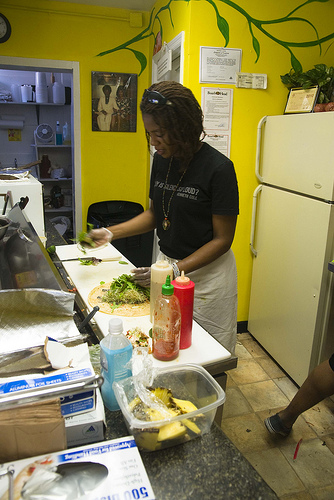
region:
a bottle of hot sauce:
[151, 273, 181, 361]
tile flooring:
[258, 448, 332, 495]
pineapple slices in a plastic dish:
[124, 348, 227, 449]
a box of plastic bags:
[2, 427, 148, 497]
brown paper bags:
[4, 395, 66, 458]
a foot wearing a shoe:
[261, 408, 300, 441]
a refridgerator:
[247, 109, 332, 383]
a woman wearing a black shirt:
[139, 139, 242, 262]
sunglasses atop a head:
[139, 84, 180, 109]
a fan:
[32, 121, 56, 145]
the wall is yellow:
[85, 135, 150, 194]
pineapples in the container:
[113, 376, 229, 457]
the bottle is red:
[172, 265, 201, 371]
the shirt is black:
[129, 143, 238, 270]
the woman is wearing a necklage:
[118, 85, 190, 235]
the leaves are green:
[72, 258, 157, 319]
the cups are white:
[31, 70, 57, 113]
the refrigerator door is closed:
[248, 133, 320, 362]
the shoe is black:
[249, 398, 316, 458]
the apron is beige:
[149, 227, 248, 364]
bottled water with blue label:
[98, 314, 135, 414]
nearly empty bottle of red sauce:
[148, 266, 184, 363]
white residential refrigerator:
[245, 97, 332, 395]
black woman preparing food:
[71, 68, 234, 313]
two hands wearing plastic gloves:
[74, 216, 185, 313]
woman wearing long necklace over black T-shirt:
[133, 76, 209, 262]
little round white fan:
[30, 117, 57, 149]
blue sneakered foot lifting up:
[260, 391, 299, 444]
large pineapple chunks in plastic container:
[111, 360, 224, 441]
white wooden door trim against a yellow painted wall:
[72, 58, 91, 204]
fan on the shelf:
[35, 123, 62, 153]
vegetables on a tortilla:
[60, 223, 183, 347]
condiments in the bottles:
[130, 236, 209, 379]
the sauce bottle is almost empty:
[145, 265, 182, 365]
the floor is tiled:
[222, 336, 285, 482]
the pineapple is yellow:
[125, 393, 204, 445]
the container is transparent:
[101, 362, 205, 458]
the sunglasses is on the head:
[129, 82, 227, 144]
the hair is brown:
[129, 75, 216, 152]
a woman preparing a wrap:
[68, 74, 250, 377]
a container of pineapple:
[118, 362, 223, 451]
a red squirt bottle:
[169, 268, 199, 352]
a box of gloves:
[2, 434, 171, 498]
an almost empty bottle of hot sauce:
[141, 272, 182, 362]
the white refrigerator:
[251, 112, 331, 390]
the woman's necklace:
[157, 158, 189, 232]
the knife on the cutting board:
[49, 252, 124, 268]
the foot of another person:
[263, 348, 332, 450]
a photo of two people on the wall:
[85, 61, 143, 142]